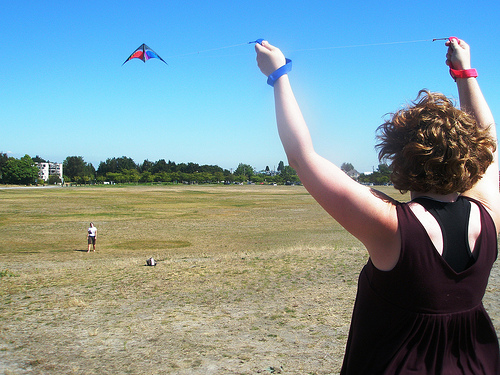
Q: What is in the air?
A: A kite.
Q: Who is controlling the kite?
A: The woman.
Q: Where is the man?
A: In the field.